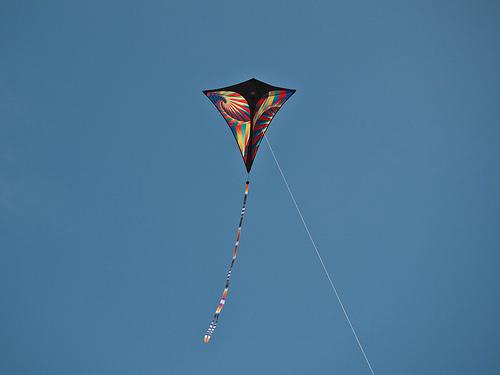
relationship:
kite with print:
[198, 75, 298, 200] [219, 93, 248, 123]